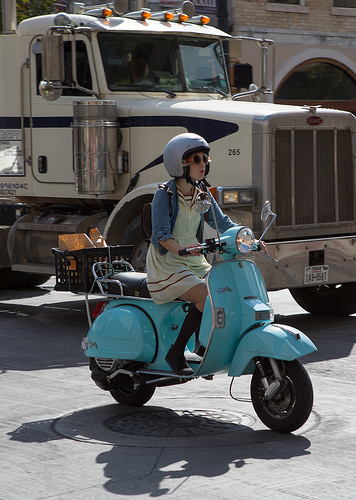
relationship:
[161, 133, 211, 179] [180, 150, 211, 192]
helmet is on head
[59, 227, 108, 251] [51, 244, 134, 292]
paper bag are inside basket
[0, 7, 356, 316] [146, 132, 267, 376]
truck drives next to girl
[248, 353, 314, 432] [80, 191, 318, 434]
tire on bike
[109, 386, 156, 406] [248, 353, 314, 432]
tire on tire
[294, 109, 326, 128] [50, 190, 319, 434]
headlight on moped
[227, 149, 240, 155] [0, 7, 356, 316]
numbers on truck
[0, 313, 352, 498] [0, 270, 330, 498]
concrete on road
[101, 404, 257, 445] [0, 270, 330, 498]
manhole cover on road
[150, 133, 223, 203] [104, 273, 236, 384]
girl on scooter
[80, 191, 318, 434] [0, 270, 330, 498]
bike on road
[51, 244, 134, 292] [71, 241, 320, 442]
basket on scooter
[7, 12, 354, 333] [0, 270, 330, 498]
truck on road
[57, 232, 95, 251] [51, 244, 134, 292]
paper bag in basket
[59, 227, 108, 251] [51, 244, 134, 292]
paper bag in basket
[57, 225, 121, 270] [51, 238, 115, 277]
items in basket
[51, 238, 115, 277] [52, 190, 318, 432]
basket on bike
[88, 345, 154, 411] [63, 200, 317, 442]
tire on bike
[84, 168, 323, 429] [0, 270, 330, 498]
bike on road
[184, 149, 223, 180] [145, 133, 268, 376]
sunglasses on girl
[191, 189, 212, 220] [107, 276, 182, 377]
mirror on bike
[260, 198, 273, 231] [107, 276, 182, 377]
mirror on bike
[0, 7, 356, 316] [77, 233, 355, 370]
truck by bike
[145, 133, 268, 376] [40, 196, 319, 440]
girl on scooter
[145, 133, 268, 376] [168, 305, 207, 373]
girl on socks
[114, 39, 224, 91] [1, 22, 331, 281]
windshield on trucks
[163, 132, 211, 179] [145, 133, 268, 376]
helmet on girl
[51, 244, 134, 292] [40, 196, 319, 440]
basket tied to scooter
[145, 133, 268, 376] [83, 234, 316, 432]
girl riding scooter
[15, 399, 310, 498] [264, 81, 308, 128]
shadow on ground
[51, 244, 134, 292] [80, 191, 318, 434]
basket on bike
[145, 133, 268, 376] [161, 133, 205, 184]
girl wears helmet